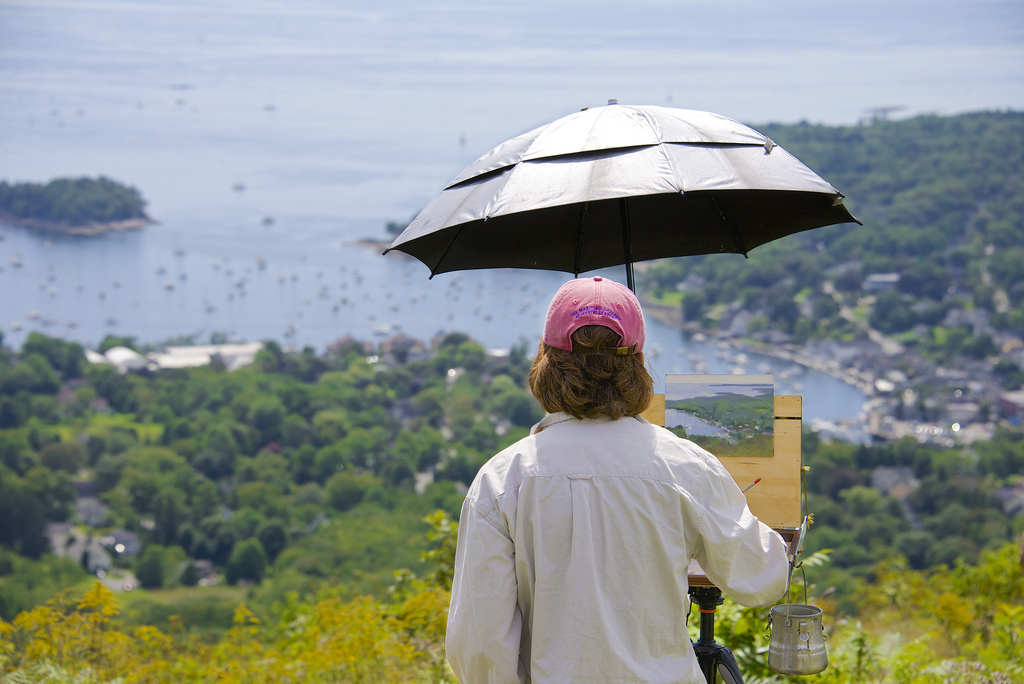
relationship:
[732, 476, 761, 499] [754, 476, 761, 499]
pen has tip